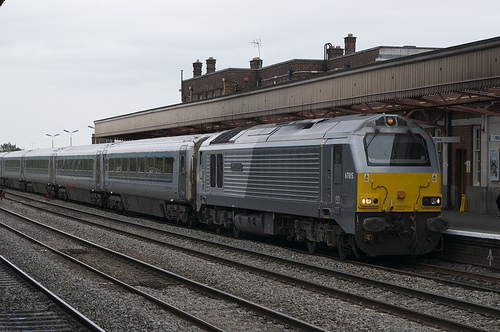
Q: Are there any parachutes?
A: No, there are no parachutes.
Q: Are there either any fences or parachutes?
A: No, there are no parachutes or fences.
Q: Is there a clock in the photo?
A: No, there are no clocks.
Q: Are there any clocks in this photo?
A: No, there are no clocks.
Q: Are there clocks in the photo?
A: No, there are no clocks.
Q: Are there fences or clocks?
A: No, there are no clocks or fences.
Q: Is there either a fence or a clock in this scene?
A: No, there are no clocks or fences.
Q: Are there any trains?
A: Yes, there is a train.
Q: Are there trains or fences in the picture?
A: Yes, there is a train.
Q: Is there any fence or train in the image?
A: Yes, there is a train.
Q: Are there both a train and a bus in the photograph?
A: No, there is a train but no buses.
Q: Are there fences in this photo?
A: No, there are no fences.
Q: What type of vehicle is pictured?
A: The vehicle is a train.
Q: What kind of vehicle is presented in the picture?
A: The vehicle is a train.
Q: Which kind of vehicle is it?
A: The vehicle is a train.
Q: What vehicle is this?
A: This is a train.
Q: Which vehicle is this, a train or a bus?
A: This is a train.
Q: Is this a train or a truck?
A: This is a train.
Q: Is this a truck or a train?
A: This is a train.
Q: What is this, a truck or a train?
A: This is a train.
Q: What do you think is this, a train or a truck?
A: This is a train.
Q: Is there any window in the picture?
A: Yes, there is a window.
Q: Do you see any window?
A: Yes, there is a window.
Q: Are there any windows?
A: Yes, there is a window.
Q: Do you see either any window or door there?
A: Yes, there is a window.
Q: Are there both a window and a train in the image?
A: Yes, there are both a window and a train.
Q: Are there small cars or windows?
A: Yes, there is a small window.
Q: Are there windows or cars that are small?
A: Yes, the window is small.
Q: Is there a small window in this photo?
A: Yes, there is a small window.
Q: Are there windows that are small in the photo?
A: Yes, there is a small window.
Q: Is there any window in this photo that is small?
A: Yes, there is a window that is small.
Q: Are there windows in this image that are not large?
A: Yes, there is a small window.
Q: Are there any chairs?
A: No, there are no chairs.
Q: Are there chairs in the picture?
A: No, there are no chairs.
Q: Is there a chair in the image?
A: No, there are no chairs.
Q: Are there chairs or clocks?
A: No, there are no chairs or clocks.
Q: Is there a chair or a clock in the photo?
A: No, there are no chairs or clocks.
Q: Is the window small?
A: Yes, the window is small.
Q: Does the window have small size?
A: Yes, the window is small.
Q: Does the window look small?
A: Yes, the window is small.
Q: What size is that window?
A: The window is small.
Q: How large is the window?
A: The window is small.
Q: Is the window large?
A: No, the window is small.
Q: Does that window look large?
A: No, the window is small.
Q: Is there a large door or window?
A: No, there is a window but it is small.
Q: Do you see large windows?
A: No, there is a window but it is small.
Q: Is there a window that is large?
A: No, there is a window but it is small.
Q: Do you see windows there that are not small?
A: No, there is a window but it is small.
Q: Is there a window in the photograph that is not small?
A: No, there is a window but it is small.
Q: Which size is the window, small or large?
A: The window is small.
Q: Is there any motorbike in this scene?
A: No, there are no motorcycles.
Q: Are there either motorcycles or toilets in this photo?
A: No, there are no motorcycles or toilets.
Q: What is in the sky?
A: The clouds are in the sky.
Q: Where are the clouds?
A: The clouds are in the sky.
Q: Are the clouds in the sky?
A: Yes, the clouds are in the sky.